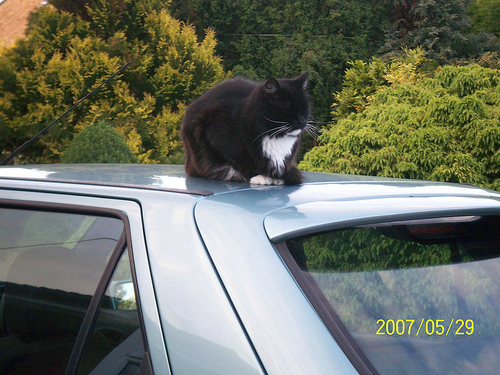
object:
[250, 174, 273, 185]
paws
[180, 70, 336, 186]
cat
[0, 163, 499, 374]
car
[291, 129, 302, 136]
fur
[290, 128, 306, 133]
cat's mouth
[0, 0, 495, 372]
photo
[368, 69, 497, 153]
bushes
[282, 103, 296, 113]
eye